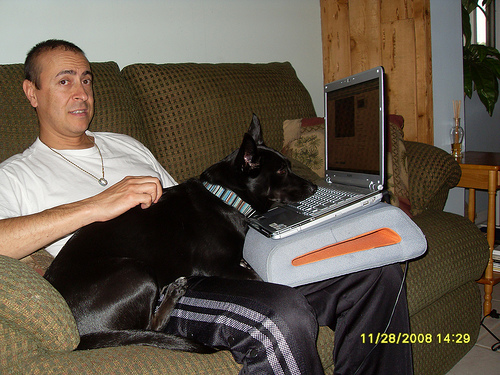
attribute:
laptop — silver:
[291, 61, 395, 212]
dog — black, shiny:
[1, 120, 318, 327]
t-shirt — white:
[2, 131, 180, 258]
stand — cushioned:
[220, 194, 434, 286]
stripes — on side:
[148, 285, 303, 373]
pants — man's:
[137, 232, 419, 372]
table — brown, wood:
[456, 149, 498, 319]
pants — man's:
[158, 263, 415, 373]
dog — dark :
[40, 118, 330, 353]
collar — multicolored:
[203, 179, 256, 221]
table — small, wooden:
[459, 150, 497, 227]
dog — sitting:
[27, 108, 324, 361]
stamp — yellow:
[361, 331, 474, 345]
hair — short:
[15, 33, 89, 81]